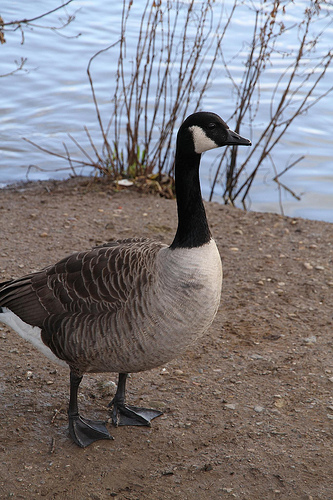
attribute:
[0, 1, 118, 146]
water — fresh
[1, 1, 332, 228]
water — nearby, background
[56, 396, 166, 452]
feet — black, webbed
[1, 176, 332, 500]
ground — sandy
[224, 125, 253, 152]
beak — black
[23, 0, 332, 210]
vegetation — reeds, growing, sticks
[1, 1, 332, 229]
background — water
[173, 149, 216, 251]
neck — black, long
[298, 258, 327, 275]
rocks — few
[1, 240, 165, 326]
back — black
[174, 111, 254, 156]
head — black, white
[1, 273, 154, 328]
wing — brown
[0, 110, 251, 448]
bird — standing, goose, canadian, wild